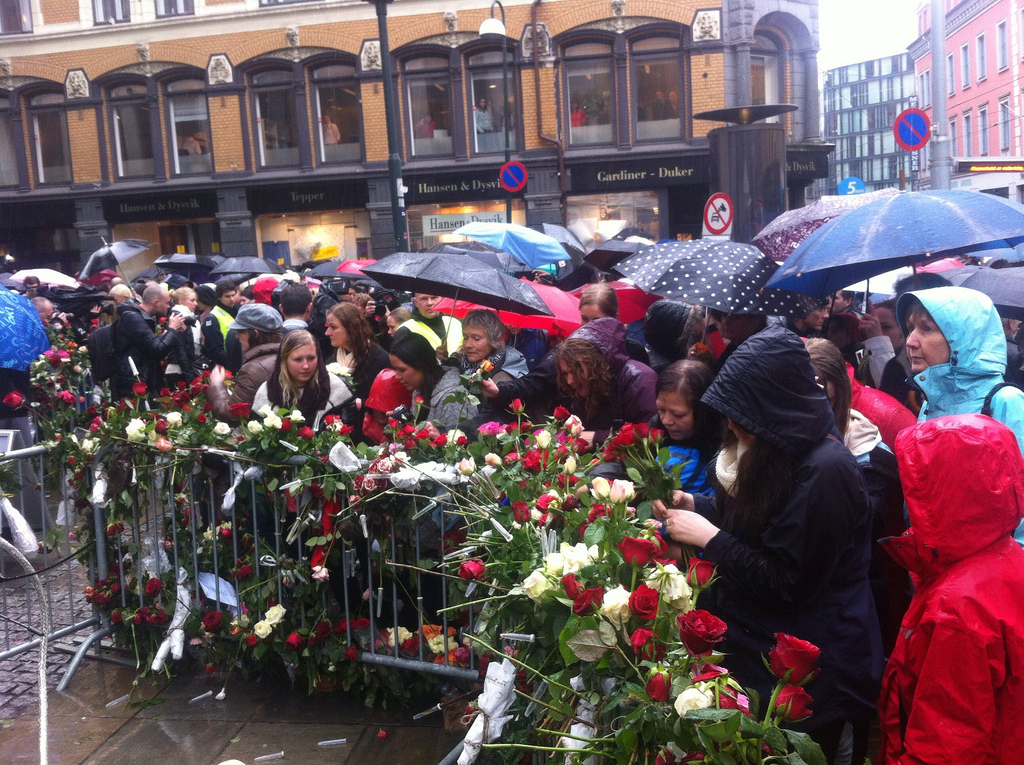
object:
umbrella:
[603, 233, 831, 333]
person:
[881, 401, 1024, 756]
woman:
[654, 326, 878, 759]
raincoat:
[699, 322, 890, 742]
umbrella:
[762, 175, 1020, 309]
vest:
[400, 311, 468, 360]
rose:
[164, 410, 184, 429]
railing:
[79, 423, 692, 757]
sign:
[499, 161, 527, 192]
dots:
[687, 257, 703, 275]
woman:
[169, 285, 207, 378]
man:
[87, 282, 199, 411]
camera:
[172, 308, 199, 327]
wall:
[903, 2, 1005, 179]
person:
[430, 310, 531, 412]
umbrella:
[353, 251, 548, 318]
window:
[545, 24, 707, 166]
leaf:
[321, 638, 343, 663]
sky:
[810, 0, 917, 62]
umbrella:
[8, 282, 62, 383]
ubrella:
[424, 282, 615, 350]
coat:
[436, 341, 546, 434]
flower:
[770, 634, 827, 682]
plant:
[243, 417, 263, 433]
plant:
[44, 390, 76, 406]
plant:
[507, 495, 532, 520]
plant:
[677, 612, 724, 648]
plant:
[310, 568, 327, 586]